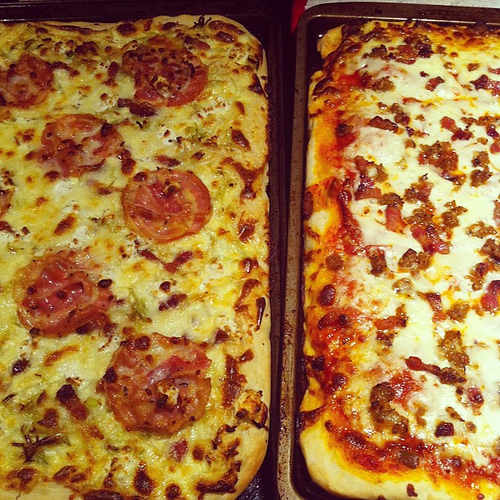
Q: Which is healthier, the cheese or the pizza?
A: The cheese is healthier than the pizza.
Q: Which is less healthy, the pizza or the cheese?
A: The pizza is less healthy than the cheese.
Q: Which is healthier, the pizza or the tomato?
A: The tomato is healthier than the pizza.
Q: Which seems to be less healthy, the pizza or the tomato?
A: The pizza is less healthy than the tomato.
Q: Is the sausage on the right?
A: Yes, the sausage is on the right of the image.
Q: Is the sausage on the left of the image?
A: No, the sausage is on the right of the image.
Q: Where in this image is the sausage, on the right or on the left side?
A: The sausage is on the right of the image.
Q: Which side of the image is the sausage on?
A: The sausage is on the right of the image.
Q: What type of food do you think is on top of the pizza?
A: The food is a sausage.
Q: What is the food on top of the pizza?
A: The food is a sausage.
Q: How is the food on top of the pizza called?
A: The food is a sausage.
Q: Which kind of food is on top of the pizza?
A: The food is a sausage.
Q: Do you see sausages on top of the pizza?
A: Yes, there is a sausage on top of the pizza.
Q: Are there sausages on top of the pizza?
A: Yes, there is a sausage on top of the pizza.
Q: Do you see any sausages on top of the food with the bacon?
A: Yes, there is a sausage on top of the pizza.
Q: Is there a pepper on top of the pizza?
A: No, there is a sausage on top of the pizza.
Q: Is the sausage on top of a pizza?
A: Yes, the sausage is on top of a pizza.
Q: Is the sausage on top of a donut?
A: No, the sausage is on top of a pizza.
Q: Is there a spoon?
A: No, there are no spoons.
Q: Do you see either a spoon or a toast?
A: No, there are no spoons or toasts.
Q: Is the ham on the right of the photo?
A: Yes, the ham is on the right of the image.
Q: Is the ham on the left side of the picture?
A: No, the ham is on the right of the image.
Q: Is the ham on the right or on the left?
A: The ham is on the right of the image.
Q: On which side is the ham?
A: The ham is on the right of the image.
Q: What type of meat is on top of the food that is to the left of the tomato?
A: The meat is ham.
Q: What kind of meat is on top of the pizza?
A: The meat is ham.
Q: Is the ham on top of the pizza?
A: Yes, the ham is on top of the pizza.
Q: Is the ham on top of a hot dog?
A: No, the ham is on top of the pizza.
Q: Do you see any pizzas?
A: Yes, there is a pizza.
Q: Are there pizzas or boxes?
A: Yes, there is a pizza.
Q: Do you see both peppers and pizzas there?
A: No, there is a pizza but no peppers.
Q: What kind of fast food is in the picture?
A: The fast food is a pizza.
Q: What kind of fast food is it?
A: The food is a pizza.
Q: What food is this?
A: That is a pizza.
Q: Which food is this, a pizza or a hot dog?
A: That is a pizza.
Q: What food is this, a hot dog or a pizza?
A: That is a pizza.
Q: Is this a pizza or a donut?
A: This is a pizza.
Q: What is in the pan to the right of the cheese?
A: The pizza is in the pan.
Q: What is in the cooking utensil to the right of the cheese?
A: The pizza is in the pan.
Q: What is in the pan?
A: The pizza is in the pan.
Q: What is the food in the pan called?
A: The food is a pizza.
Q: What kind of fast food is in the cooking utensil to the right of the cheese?
A: The food is a pizza.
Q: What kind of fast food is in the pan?
A: The food is a pizza.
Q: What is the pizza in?
A: The pizza is in the pan.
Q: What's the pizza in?
A: The pizza is in the pan.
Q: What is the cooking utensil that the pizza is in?
A: The cooking utensil is a pan.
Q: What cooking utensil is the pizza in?
A: The pizza is in the pan.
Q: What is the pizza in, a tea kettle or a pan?
A: The pizza is in a pan.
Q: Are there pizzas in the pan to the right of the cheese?
A: Yes, there is a pizza in the pan.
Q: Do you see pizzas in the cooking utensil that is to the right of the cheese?
A: Yes, there is a pizza in the pan.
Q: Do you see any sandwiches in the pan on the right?
A: No, there is a pizza in the pan.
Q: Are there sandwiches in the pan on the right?
A: No, there is a pizza in the pan.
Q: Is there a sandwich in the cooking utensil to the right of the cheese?
A: No, there is a pizza in the pan.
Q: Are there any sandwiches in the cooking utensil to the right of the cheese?
A: No, there is a pizza in the pan.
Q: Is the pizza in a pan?
A: Yes, the pizza is in a pan.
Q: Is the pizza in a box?
A: No, the pizza is in a pan.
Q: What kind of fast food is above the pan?
A: The food is a pizza.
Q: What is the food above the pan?
A: The food is a pizza.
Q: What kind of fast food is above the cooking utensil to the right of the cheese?
A: The food is a pizza.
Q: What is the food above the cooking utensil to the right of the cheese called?
A: The food is a pizza.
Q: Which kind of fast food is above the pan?
A: The food is a pizza.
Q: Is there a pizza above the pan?
A: Yes, there is a pizza above the pan.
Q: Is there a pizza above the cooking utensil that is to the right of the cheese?
A: Yes, there is a pizza above the pan.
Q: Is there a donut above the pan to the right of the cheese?
A: No, there is a pizza above the pan.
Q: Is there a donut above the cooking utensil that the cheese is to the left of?
A: No, there is a pizza above the pan.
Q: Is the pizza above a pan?
A: Yes, the pizza is above a pan.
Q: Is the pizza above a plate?
A: No, the pizza is above a pan.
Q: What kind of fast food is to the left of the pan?
A: The food is a pizza.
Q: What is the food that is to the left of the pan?
A: The food is a pizza.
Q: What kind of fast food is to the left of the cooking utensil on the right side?
A: The food is a pizza.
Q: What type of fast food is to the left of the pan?
A: The food is a pizza.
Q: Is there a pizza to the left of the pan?
A: Yes, there is a pizza to the left of the pan.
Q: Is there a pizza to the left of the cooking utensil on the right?
A: Yes, there is a pizza to the left of the pan.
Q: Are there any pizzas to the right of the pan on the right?
A: No, the pizza is to the left of the pan.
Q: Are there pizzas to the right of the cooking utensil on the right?
A: No, the pizza is to the left of the pan.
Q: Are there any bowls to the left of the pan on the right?
A: No, there is a pizza to the left of the pan.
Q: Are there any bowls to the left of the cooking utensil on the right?
A: No, there is a pizza to the left of the pan.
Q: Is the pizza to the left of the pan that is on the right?
A: Yes, the pizza is to the left of the pan.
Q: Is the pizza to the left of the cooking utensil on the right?
A: Yes, the pizza is to the left of the pan.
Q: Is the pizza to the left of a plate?
A: No, the pizza is to the left of the pan.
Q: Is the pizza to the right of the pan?
A: No, the pizza is to the left of the pan.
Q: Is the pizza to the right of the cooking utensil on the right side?
A: No, the pizza is to the left of the pan.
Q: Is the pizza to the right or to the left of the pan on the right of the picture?
A: The pizza is to the left of the pan.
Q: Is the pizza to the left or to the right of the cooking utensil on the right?
A: The pizza is to the left of the pan.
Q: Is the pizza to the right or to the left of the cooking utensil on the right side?
A: The pizza is to the left of the pan.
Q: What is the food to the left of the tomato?
A: The food is a pizza.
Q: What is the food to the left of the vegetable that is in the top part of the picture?
A: The food is a pizza.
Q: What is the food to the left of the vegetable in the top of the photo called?
A: The food is a pizza.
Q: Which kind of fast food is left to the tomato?
A: The food is a pizza.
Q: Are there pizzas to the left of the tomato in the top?
A: Yes, there is a pizza to the left of the tomato.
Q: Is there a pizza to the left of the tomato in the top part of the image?
A: Yes, there is a pizza to the left of the tomato.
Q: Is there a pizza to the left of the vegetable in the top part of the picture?
A: Yes, there is a pizza to the left of the tomato.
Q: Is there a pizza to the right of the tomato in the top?
A: No, the pizza is to the left of the tomato.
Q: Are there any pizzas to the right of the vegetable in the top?
A: No, the pizza is to the left of the tomato.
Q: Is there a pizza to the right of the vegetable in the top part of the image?
A: No, the pizza is to the left of the tomato.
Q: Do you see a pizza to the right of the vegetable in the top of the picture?
A: No, the pizza is to the left of the tomato.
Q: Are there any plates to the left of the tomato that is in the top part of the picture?
A: No, there is a pizza to the left of the tomato.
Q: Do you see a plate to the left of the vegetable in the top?
A: No, there is a pizza to the left of the tomato.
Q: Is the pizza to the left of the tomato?
A: Yes, the pizza is to the left of the tomato.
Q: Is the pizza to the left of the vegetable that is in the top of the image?
A: Yes, the pizza is to the left of the tomato.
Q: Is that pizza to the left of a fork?
A: No, the pizza is to the left of the tomato.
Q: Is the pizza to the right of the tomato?
A: No, the pizza is to the left of the tomato.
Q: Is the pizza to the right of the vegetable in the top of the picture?
A: No, the pizza is to the left of the tomato.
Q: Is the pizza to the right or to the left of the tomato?
A: The pizza is to the left of the tomato.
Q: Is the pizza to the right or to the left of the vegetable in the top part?
A: The pizza is to the left of the tomato.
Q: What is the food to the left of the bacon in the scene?
A: The food is a pizza.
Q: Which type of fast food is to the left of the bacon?
A: The food is a pizza.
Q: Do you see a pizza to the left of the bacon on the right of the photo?
A: Yes, there is a pizza to the left of the bacon.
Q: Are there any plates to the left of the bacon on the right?
A: No, there is a pizza to the left of the bacon.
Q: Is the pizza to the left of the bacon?
A: Yes, the pizza is to the left of the bacon.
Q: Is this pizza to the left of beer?
A: No, the pizza is to the left of the bacon.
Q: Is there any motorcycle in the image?
A: No, there are no motorcycles.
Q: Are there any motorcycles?
A: No, there are no motorcycles.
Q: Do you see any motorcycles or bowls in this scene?
A: No, there are no motorcycles or bowls.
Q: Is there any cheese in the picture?
A: Yes, there is cheese.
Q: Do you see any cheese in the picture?
A: Yes, there is cheese.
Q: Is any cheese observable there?
A: Yes, there is cheese.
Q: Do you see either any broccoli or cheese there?
A: Yes, there is cheese.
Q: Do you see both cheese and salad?
A: No, there is cheese but no salad.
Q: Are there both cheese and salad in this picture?
A: No, there is cheese but no salad.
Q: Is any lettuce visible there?
A: No, there is no lettuce.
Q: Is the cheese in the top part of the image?
A: Yes, the cheese is in the top of the image.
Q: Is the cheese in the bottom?
A: No, the cheese is in the top of the image.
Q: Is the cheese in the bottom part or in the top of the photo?
A: The cheese is in the top of the image.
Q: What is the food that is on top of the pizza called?
A: The food is cheese.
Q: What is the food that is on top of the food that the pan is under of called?
A: The food is cheese.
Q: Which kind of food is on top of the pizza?
A: The food is cheese.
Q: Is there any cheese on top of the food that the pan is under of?
A: Yes, there is cheese on top of the pizza.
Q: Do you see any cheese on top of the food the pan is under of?
A: Yes, there is cheese on top of the pizza.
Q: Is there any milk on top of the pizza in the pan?
A: No, there is cheese on top of the pizza.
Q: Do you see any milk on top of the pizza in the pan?
A: No, there is cheese on top of the pizza.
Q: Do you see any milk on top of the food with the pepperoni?
A: No, there is cheese on top of the pizza.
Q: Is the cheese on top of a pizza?
A: Yes, the cheese is on top of a pizza.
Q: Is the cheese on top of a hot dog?
A: No, the cheese is on top of a pizza.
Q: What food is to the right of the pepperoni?
A: The food is cheese.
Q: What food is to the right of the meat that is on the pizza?
A: The food is cheese.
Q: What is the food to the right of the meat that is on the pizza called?
A: The food is cheese.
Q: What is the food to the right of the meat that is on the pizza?
A: The food is cheese.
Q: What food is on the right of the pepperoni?
A: The food is cheese.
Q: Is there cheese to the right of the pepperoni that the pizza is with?
A: Yes, there is cheese to the right of the pepperoni.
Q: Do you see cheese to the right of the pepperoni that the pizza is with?
A: Yes, there is cheese to the right of the pepperoni.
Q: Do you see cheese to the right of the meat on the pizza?
A: Yes, there is cheese to the right of the pepperoni.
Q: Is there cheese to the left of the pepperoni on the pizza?
A: No, the cheese is to the right of the pepperoni.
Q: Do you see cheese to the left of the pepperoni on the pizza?
A: No, the cheese is to the right of the pepperoni.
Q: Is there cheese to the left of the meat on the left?
A: No, the cheese is to the right of the pepperoni.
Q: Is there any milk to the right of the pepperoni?
A: No, there is cheese to the right of the pepperoni.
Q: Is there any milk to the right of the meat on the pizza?
A: No, there is cheese to the right of the pepperoni.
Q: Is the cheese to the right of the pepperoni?
A: Yes, the cheese is to the right of the pepperoni.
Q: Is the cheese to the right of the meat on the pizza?
A: Yes, the cheese is to the right of the pepperoni.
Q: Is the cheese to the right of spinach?
A: No, the cheese is to the right of the pepperoni.